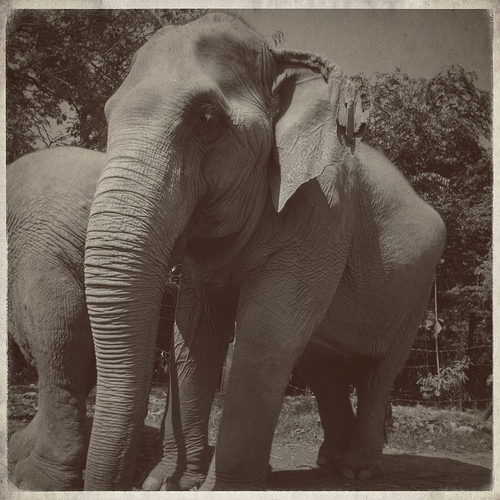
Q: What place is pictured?
A: It is a park.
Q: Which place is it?
A: It is a park.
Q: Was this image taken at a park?
A: Yes, it was taken in a park.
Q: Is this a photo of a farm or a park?
A: It is showing a park.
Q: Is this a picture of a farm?
A: No, the picture is showing a park.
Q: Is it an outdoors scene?
A: Yes, it is outdoors.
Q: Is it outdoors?
A: Yes, it is outdoors.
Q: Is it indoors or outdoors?
A: It is outdoors.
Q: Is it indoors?
A: No, it is outdoors.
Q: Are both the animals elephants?
A: Yes, all the animals are elephants.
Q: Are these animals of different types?
A: No, all the animals are elephants.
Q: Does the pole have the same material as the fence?
A: No, the pole is made of wood and the fence is made of metal.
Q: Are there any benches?
A: No, there are no benches.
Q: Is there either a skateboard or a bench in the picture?
A: No, there are no benches or skateboards.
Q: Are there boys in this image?
A: No, there are no boys.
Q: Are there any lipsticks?
A: No, there are no lipsticks.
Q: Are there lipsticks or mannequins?
A: No, there are no lipsticks or mannequins.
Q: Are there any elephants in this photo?
A: Yes, there is an elephant.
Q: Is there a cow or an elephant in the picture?
A: Yes, there is an elephant.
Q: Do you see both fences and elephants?
A: Yes, there are both an elephant and a fence.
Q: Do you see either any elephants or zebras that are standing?
A: Yes, the elephant is standing.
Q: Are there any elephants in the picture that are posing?
A: Yes, there is an elephant that is posing.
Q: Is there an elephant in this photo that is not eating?
A: Yes, there is an elephant that is posing.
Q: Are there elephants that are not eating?
A: Yes, there is an elephant that is posing.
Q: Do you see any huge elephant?
A: Yes, there is a huge elephant.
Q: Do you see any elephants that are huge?
A: Yes, there is an elephant that is huge.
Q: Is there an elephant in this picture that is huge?
A: Yes, there is an elephant that is huge.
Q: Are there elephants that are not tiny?
A: Yes, there is a huge elephant.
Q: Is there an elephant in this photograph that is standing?
A: Yes, there is an elephant that is standing.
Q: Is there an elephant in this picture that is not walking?
A: Yes, there is an elephant that is standing.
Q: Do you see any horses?
A: No, there are no horses.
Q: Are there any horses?
A: No, there are no horses.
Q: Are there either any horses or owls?
A: No, there are no horses or owls.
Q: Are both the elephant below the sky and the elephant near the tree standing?
A: Yes, both the elephant and the elephant are standing.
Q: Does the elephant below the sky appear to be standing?
A: Yes, the elephant is standing.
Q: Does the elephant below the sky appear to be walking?
A: No, the elephant is standing.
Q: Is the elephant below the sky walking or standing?
A: The elephant is standing.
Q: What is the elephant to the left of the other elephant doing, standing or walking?
A: The elephant is standing.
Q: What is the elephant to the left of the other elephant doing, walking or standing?
A: The elephant is standing.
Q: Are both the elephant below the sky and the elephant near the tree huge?
A: Yes, both the elephant and the elephant are huge.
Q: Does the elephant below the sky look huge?
A: Yes, the elephant is huge.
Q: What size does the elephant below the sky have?
A: The elephant has huge size.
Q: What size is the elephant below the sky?
A: The elephant is huge.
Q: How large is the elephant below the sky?
A: The elephant is huge.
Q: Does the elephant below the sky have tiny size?
A: No, the elephant is huge.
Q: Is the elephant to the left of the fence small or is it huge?
A: The elephant is huge.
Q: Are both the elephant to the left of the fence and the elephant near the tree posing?
A: Yes, both the elephant and the elephant are posing.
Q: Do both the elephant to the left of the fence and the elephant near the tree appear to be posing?
A: Yes, both the elephant and the elephant are posing.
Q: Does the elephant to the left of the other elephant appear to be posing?
A: Yes, the elephant is posing.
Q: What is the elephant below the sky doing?
A: The elephant is posing.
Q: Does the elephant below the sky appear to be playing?
A: No, the elephant is posing.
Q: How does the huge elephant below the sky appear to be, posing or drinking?
A: The elephant is posing.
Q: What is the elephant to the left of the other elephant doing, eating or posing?
A: The elephant is posing.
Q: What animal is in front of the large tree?
A: The elephant is in front of the tree.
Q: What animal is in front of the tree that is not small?
A: The animal is an elephant.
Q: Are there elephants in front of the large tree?
A: Yes, there is an elephant in front of the tree.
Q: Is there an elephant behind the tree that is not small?
A: No, the elephant is in front of the tree.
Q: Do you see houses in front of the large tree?
A: No, there is an elephant in front of the tree.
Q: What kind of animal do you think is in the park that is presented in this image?
A: The animal is an elephant.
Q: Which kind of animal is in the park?
A: The animal is an elephant.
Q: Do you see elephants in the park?
A: Yes, there is an elephant in the park.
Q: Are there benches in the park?
A: No, there is an elephant in the park.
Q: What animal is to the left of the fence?
A: The animal is an elephant.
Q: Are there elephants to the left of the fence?
A: Yes, there is an elephant to the left of the fence.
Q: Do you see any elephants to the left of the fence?
A: Yes, there is an elephant to the left of the fence.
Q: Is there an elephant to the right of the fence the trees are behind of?
A: No, the elephant is to the left of the fence.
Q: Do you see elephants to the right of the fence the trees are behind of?
A: No, the elephant is to the left of the fence.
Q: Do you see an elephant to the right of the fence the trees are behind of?
A: No, the elephant is to the left of the fence.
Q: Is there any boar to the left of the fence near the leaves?
A: No, there is an elephant to the left of the fence.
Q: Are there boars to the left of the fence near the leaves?
A: No, there is an elephant to the left of the fence.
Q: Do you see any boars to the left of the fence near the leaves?
A: No, there is an elephant to the left of the fence.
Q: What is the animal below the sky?
A: The animal is an elephant.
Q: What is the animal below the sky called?
A: The animal is an elephant.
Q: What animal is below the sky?
A: The animal is an elephant.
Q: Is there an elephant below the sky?
A: Yes, there is an elephant below the sky.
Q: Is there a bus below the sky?
A: No, there is an elephant below the sky.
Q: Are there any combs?
A: No, there are no combs.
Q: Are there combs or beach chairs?
A: No, there are no combs or beach chairs.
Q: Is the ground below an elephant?
A: Yes, the ground is below an elephant.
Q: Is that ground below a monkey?
A: No, the ground is below an elephant.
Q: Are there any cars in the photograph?
A: No, there are no cars.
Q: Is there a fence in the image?
A: Yes, there is a fence.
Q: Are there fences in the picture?
A: Yes, there is a fence.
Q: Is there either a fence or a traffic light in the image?
A: Yes, there is a fence.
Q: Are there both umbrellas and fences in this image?
A: No, there is a fence but no umbrellas.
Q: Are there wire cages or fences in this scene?
A: Yes, there is a wire fence.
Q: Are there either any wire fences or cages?
A: Yes, there is a wire fence.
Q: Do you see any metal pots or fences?
A: Yes, there is a metal fence.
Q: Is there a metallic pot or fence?
A: Yes, there is a metal fence.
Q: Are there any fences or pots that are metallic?
A: Yes, the fence is metallic.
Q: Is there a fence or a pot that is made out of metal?
A: Yes, the fence is made of metal.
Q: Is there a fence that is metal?
A: Yes, there is a metal fence.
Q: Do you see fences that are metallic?
A: Yes, there is a fence that is metallic.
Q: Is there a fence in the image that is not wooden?
A: Yes, there is a metallic fence.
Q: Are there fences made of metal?
A: Yes, there is a fence that is made of metal.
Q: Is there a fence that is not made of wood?
A: Yes, there is a fence that is made of metal.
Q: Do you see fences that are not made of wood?
A: Yes, there is a fence that is made of metal.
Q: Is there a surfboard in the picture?
A: No, there are no surfboards.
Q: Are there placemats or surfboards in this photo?
A: No, there are no surfboards or placemats.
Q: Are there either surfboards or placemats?
A: No, there are no surfboards or placemats.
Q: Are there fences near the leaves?
A: Yes, there is a fence near the leaves.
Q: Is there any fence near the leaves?
A: Yes, there is a fence near the leaves.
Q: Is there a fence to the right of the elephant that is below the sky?
A: Yes, there is a fence to the right of the elephant.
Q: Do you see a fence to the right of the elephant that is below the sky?
A: Yes, there is a fence to the right of the elephant.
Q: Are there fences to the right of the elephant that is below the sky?
A: Yes, there is a fence to the right of the elephant.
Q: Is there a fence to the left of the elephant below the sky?
A: No, the fence is to the right of the elephant.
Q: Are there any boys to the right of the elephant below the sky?
A: No, there is a fence to the right of the elephant.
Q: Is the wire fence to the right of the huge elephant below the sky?
A: Yes, the fence is to the right of the elephant.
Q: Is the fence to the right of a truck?
A: No, the fence is to the right of the elephant.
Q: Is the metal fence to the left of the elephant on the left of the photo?
A: No, the fence is to the right of the elephant.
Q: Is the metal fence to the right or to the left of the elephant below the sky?
A: The fence is to the right of the elephant.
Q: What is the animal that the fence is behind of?
A: The animal is an elephant.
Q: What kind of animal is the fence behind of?
A: The fence is behind the elephant.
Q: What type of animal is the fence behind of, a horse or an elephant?
A: The fence is behind an elephant.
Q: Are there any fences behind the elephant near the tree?
A: Yes, there is a fence behind the elephant.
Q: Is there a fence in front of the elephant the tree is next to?
A: No, the fence is behind the elephant.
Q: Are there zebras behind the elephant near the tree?
A: No, there is a fence behind the elephant.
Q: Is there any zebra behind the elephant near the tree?
A: No, there is a fence behind the elephant.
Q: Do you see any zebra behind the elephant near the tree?
A: No, there is a fence behind the elephant.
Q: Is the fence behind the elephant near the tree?
A: Yes, the fence is behind the elephant.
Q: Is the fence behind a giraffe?
A: No, the fence is behind the elephant.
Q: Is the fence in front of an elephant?
A: No, the fence is behind an elephant.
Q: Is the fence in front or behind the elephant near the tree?
A: The fence is behind the elephant.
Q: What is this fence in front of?
A: The fence is in front of the trees.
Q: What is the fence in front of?
A: The fence is in front of the trees.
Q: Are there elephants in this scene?
A: Yes, there is an elephant.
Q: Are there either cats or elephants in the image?
A: Yes, there is an elephant.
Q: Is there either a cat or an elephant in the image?
A: Yes, there is an elephant.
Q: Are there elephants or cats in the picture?
A: Yes, there is an elephant.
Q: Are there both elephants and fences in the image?
A: Yes, there are both an elephant and a fence.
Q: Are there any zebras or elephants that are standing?
A: Yes, the elephant is standing.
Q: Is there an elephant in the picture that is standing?
A: Yes, there is an elephant that is standing.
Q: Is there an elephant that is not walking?
A: Yes, there is an elephant that is standing.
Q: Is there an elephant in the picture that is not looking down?
A: Yes, there is an elephant that is posing.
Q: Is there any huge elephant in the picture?
A: Yes, there is a huge elephant.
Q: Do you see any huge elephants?
A: Yes, there is a huge elephant.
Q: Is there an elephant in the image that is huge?
A: Yes, there is an elephant that is huge.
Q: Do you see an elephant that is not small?
A: Yes, there is a huge elephant.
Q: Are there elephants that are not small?
A: Yes, there is a huge elephant.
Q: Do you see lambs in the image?
A: No, there are no lambs.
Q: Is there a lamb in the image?
A: No, there are no lambs.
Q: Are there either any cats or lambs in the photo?
A: No, there are no lambs or cats.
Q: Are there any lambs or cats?
A: No, there are no lambs or cats.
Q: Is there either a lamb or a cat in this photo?
A: No, there are no lambs or cats.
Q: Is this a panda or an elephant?
A: This is an elephant.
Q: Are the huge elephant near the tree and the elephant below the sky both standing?
A: Yes, both the elephant and the elephant are standing.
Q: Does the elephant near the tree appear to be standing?
A: Yes, the elephant is standing.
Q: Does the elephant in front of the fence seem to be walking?
A: No, the elephant is standing.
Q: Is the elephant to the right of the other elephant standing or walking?
A: The elephant is standing.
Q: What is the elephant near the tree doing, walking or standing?
A: The elephant is standing.